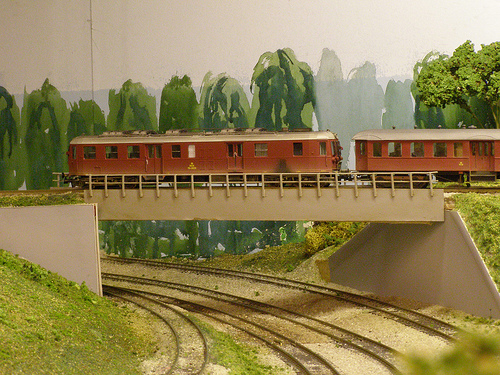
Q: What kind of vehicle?
A: Train.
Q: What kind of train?
A: Toy.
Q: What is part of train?
A: Car.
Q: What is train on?
A: Bridge.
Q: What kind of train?
A: Miniature.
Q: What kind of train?
A: Passenger.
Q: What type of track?
A: Train track.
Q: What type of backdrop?
A: Painted.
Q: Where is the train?
A: On the bridge.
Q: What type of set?
A: Train set.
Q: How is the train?
A: Brown and painted.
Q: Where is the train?
A: Over the tracks.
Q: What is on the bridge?
A: Train.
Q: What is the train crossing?
A: Bridge.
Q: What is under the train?
A: Tracks.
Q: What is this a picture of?
A: Model train.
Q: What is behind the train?
A: Trees.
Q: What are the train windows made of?
A: Plastic.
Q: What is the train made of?
A: Metal.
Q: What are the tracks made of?
A: Metal.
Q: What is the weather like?
A: Sunny.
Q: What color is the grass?
A: Green.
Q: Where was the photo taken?
A: Next to a bridge.